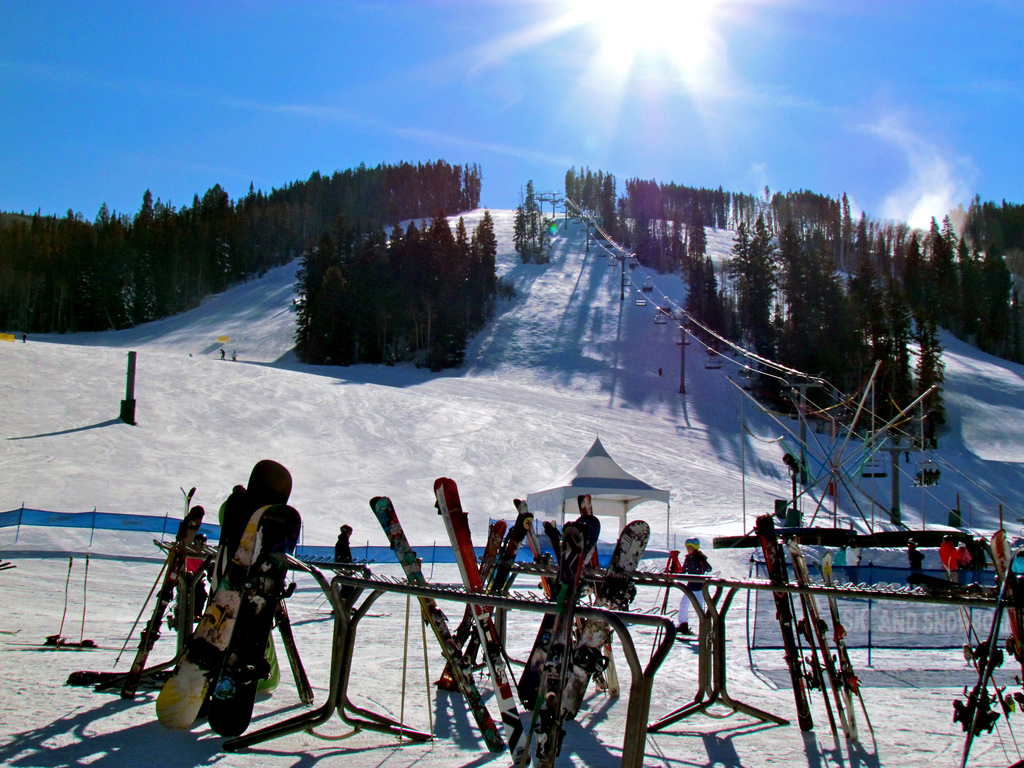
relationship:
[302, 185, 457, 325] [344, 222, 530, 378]
tree in a field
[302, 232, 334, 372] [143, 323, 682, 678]
tree in a field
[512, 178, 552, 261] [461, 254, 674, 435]
tree in a field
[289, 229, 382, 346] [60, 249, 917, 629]
tree in a field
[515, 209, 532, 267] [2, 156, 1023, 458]
tree in a field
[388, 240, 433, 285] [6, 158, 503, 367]
leaves on tree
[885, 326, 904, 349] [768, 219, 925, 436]
leaves on tree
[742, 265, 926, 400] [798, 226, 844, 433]
leaves on tree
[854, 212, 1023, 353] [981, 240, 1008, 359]
leaves on tree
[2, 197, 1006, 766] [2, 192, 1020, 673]
snow on slope